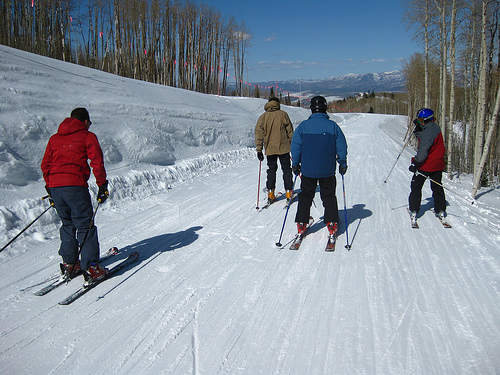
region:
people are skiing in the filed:
[61, 57, 426, 337]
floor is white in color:
[264, 250, 427, 374]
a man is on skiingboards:
[15, 101, 169, 297]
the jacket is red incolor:
[42, 112, 117, 199]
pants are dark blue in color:
[41, 197, 108, 287]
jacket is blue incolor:
[298, 118, 368, 205]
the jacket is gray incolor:
[253, 97, 295, 152]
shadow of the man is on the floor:
[120, 223, 195, 269]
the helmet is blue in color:
[397, 101, 457, 129]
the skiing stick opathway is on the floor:
[138, 312, 296, 362]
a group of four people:
[3, 90, 478, 317]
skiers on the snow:
[0, 82, 479, 312]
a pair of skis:
[14, 243, 151, 316]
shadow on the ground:
[277, 196, 377, 253]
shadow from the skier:
[20, 216, 212, 308]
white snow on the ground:
[1, 44, 498, 374]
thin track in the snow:
[182, 322, 207, 374]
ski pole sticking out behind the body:
[408, 166, 480, 212]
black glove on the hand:
[255, 148, 266, 163]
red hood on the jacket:
[51, 118, 85, 136]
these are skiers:
[30, 16, 442, 266]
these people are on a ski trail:
[65, 42, 466, 284]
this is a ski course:
[43, 53, 390, 341]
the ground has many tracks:
[161, 223, 272, 370]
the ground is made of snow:
[143, 278, 270, 362]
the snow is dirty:
[236, 250, 302, 347]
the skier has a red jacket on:
[41, 35, 129, 277]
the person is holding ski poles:
[28, 93, 75, 240]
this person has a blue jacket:
[270, 100, 358, 183]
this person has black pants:
[296, 164, 364, 217]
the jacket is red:
[36, 112, 111, 191]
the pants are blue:
[44, 194, 103, 265]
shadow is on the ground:
[133, 219, 213, 264]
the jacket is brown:
[253, 109, 292, 154]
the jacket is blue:
[285, 119, 347, 180]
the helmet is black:
[308, 92, 329, 117]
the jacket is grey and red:
[410, 124, 452, 175]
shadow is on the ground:
[336, 196, 370, 248]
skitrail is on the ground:
[186, 232, 288, 332]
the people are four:
[16, 82, 454, 300]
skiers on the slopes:
[22, 9, 458, 283]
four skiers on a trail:
[62, 77, 466, 292]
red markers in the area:
[65, 10, 299, 94]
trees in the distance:
[326, 87, 407, 124]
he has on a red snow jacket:
[28, 104, 123, 186]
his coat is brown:
[243, 92, 301, 169]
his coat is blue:
[279, 102, 361, 179]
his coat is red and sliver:
[396, 111, 462, 187]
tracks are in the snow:
[124, 195, 433, 332]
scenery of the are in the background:
[272, 56, 410, 103]